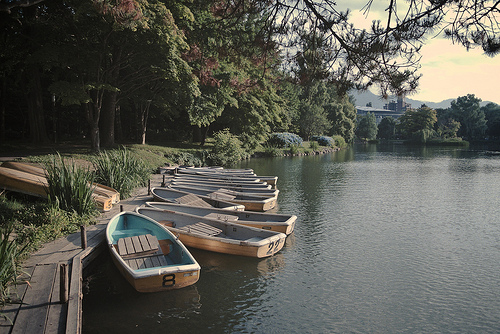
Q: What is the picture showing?
A: It is showing a river.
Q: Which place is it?
A: It is a river.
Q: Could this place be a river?
A: Yes, it is a river.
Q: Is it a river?
A: Yes, it is a river.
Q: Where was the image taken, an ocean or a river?
A: It was taken at a river.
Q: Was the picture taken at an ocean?
A: No, the picture was taken in a river.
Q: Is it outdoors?
A: Yes, it is outdoors.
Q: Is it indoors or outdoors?
A: It is outdoors.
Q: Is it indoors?
A: No, it is outdoors.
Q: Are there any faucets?
A: No, there are no faucets.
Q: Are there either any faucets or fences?
A: No, there are no faucets or fences.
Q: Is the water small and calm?
A: Yes, the water is small and calm.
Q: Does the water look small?
A: Yes, the water is small.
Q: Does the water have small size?
A: Yes, the water is small.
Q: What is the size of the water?
A: The water is small.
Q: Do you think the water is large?
A: No, the water is small.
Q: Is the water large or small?
A: The water is small.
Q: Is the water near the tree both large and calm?
A: No, the water is calm but small.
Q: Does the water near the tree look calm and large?
A: No, the water is calm but small.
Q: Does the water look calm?
A: Yes, the water is calm.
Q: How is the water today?
A: The water is calm.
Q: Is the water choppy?
A: No, the water is calm.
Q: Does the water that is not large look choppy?
A: No, the water is calm.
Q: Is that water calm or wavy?
A: The water is calm.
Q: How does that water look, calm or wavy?
A: The water is calm.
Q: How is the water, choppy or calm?
A: The water is calm.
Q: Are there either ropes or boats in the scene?
A: Yes, there is a boat.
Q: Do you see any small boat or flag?
A: Yes, there is a small boat.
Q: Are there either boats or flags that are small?
A: Yes, the boat is small.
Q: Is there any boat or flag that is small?
A: Yes, the boat is small.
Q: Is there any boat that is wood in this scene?
A: Yes, there is a wood boat.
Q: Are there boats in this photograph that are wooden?
A: Yes, there is a boat that is wooden.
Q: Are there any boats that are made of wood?
A: Yes, there is a boat that is made of wood.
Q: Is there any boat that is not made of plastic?
A: Yes, there is a boat that is made of wood.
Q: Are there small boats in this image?
A: Yes, there is a small boat.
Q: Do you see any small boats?
A: Yes, there is a small boat.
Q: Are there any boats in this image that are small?
A: Yes, there is a boat that is small.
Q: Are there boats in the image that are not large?
A: Yes, there is a small boat.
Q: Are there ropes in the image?
A: No, there are no ropes.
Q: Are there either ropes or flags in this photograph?
A: No, there are no ropes or flags.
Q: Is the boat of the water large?
A: No, the boat is small.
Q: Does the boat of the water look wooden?
A: Yes, the boat is wooden.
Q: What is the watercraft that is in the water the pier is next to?
A: The watercraft is a boat.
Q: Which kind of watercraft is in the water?
A: The watercraft is a boat.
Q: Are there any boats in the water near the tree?
A: Yes, there is a boat in the water.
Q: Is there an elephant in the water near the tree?
A: No, there is a boat in the water.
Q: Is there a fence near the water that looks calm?
A: No, there is a boat near the water.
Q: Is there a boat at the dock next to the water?
A: Yes, there is a boat at the pier.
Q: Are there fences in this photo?
A: No, there are no fences.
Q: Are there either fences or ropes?
A: No, there are no fences or ropes.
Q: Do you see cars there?
A: No, there are no cars.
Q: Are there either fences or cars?
A: No, there are no cars or fences.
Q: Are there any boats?
A: Yes, there is a boat.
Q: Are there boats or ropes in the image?
A: Yes, there is a boat.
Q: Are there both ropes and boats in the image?
A: No, there is a boat but no ropes.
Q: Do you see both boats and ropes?
A: No, there is a boat but no ropes.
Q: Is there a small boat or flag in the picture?
A: Yes, there is a small boat.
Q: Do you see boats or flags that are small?
A: Yes, the boat is small.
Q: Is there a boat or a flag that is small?
A: Yes, the boat is small.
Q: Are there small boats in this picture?
A: Yes, there is a small boat.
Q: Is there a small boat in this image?
A: Yes, there is a small boat.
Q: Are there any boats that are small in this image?
A: Yes, there is a small boat.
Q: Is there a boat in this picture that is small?
A: Yes, there is a boat that is small.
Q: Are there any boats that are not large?
A: Yes, there is a small boat.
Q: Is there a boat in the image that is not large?
A: Yes, there is a small boat.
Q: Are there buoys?
A: No, there are no buoys.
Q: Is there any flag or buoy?
A: No, there are no buoys or flags.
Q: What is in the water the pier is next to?
A: The boat is in the water.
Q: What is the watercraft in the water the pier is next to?
A: The watercraft is a boat.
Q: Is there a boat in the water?
A: Yes, there is a boat in the water.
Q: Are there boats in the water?
A: Yes, there is a boat in the water.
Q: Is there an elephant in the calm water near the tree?
A: No, there is a boat in the water.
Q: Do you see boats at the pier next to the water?
A: Yes, there is a boat at the pier.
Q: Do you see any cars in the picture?
A: No, there are no cars.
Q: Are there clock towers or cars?
A: No, there are no cars or clock towers.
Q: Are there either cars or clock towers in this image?
A: No, there are no cars or clock towers.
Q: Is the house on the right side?
A: Yes, the house is on the right of the image.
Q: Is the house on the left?
A: No, the house is on the right of the image.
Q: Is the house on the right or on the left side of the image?
A: The house is on the right of the image.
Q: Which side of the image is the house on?
A: The house is on the right of the image.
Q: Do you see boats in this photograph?
A: Yes, there is a boat.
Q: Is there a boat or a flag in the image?
A: Yes, there is a boat.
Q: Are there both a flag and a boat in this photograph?
A: No, there is a boat but no flags.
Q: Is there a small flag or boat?
A: Yes, there is a small boat.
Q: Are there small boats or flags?
A: Yes, there is a small boat.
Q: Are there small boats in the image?
A: Yes, there is a small boat.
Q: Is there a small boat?
A: Yes, there is a small boat.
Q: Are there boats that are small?
A: Yes, there is a boat that is small.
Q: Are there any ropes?
A: No, there are no ropes.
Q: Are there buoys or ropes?
A: No, there are no ropes or buoys.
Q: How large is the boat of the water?
A: The boat is small.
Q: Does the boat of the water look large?
A: No, the boat is small.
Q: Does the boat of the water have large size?
A: No, the boat is small.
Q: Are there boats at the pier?
A: Yes, there is a boat at the pier.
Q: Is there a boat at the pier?
A: Yes, there is a boat at the pier.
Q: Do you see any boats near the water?
A: Yes, there is a boat near the water.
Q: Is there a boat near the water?
A: Yes, there is a boat near the water.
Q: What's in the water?
A: The boat is in the water.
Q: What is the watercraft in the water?
A: The watercraft is a boat.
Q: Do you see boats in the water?
A: Yes, there is a boat in the water.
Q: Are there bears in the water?
A: No, there is a boat in the water.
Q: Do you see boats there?
A: Yes, there is a boat.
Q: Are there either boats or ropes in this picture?
A: Yes, there is a boat.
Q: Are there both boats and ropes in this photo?
A: No, there is a boat but no ropes.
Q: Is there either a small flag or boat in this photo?
A: Yes, there is a small boat.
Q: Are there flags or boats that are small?
A: Yes, the boat is small.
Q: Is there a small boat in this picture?
A: Yes, there is a small boat.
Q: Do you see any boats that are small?
A: Yes, there is a boat that is small.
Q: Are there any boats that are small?
A: Yes, there is a boat that is small.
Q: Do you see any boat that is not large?
A: Yes, there is a small boat.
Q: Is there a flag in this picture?
A: No, there are no flags.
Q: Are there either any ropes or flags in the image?
A: No, there are no flags or ropes.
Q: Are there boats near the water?
A: Yes, there is a boat near the water.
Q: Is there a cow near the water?
A: No, there is a boat near the water.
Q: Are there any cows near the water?
A: No, there is a boat near the water.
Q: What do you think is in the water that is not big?
A: The boat is in the water.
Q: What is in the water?
A: The boat is in the water.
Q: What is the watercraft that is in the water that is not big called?
A: The watercraft is a boat.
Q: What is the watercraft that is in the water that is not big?
A: The watercraft is a boat.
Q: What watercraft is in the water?
A: The watercraft is a boat.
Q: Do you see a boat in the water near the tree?
A: Yes, there is a boat in the water.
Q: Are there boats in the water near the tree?
A: Yes, there is a boat in the water.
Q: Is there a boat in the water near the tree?
A: Yes, there is a boat in the water.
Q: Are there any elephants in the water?
A: No, there is a boat in the water.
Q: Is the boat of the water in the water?
A: Yes, the boat is in the water.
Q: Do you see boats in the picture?
A: Yes, there is a boat.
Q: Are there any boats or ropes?
A: Yes, there is a boat.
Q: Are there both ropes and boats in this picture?
A: No, there is a boat but no ropes.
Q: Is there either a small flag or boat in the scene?
A: Yes, there is a small boat.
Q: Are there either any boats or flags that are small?
A: Yes, the boat is small.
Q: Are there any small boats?
A: Yes, there is a small boat.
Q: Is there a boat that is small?
A: Yes, there is a boat that is small.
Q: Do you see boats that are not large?
A: Yes, there is a small boat.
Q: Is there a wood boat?
A: Yes, there is a boat that is made of wood.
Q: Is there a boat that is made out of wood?
A: Yes, there is a boat that is made of wood.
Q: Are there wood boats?
A: Yes, there is a boat that is made of wood.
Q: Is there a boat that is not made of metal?
A: Yes, there is a boat that is made of wood.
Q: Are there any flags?
A: No, there are no flags.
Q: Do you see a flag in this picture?
A: No, there are no flags.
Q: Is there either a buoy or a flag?
A: No, there are no flags or buoys.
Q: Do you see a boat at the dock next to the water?
A: Yes, there is a boat at the dock.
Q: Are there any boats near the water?
A: Yes, there is a boat near the water.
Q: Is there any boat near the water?
A: Yes, there is a boat near the water.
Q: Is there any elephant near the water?
A: No, there is a boat near the water.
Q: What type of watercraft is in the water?
A: The watercraft is a boat.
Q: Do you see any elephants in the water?
A: No, there is a boat in the water.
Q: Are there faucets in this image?
A: No, there are no faucets.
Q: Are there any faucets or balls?
A: No, there are no faucets or balls.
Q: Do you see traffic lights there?
A: No, there are no traffic lights.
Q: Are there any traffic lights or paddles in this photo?
A: No, there are no traffic lights or paddles.